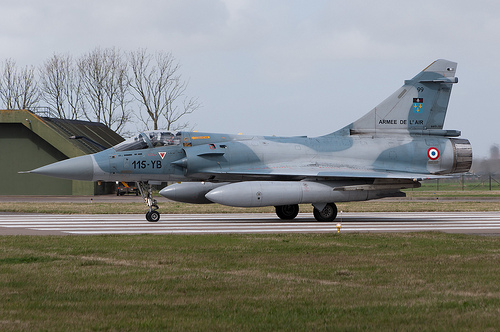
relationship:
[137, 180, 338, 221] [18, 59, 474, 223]
landing gear under jet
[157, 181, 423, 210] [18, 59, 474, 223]
missiles on jet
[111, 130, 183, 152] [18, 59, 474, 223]
cockpit in jet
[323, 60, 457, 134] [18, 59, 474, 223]
tail on jet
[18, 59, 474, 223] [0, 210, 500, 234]
jet on runway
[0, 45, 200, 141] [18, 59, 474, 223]
trees behind jet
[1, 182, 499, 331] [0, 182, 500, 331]
grass on ground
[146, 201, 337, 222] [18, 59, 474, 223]
wheels under jet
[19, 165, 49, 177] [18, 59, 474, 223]
nose on jet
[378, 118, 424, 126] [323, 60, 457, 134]
words on tail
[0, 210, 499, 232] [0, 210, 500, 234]
marks on runway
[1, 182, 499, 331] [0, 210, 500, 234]
grass around runway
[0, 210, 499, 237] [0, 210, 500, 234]
lines on runway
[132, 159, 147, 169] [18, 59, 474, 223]
numbers on jet